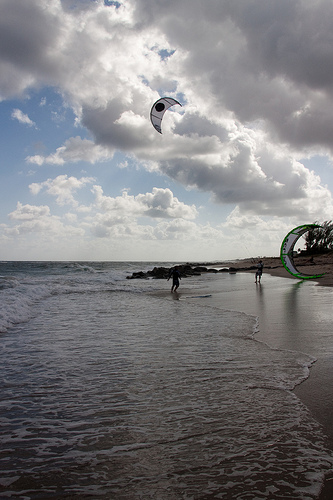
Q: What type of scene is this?
A: Beachfront.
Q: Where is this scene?
A: Beach shore.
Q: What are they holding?
A: Kites.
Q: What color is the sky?
A: Blue.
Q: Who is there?
A: 2 people.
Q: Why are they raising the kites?
A: To fly them.